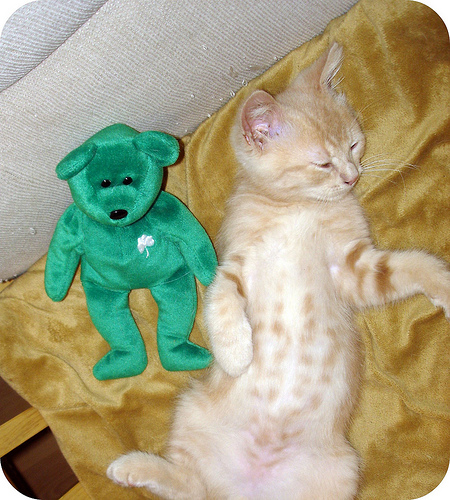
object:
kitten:
[107, 45, 449, 498]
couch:
[0, 2, 449, 497]